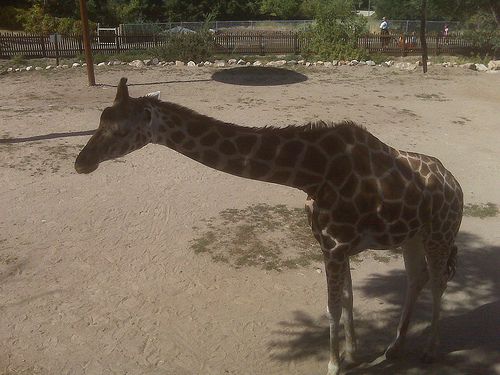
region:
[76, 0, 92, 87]
brown pole in ground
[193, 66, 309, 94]
shadow from the pole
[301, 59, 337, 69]
rocks on the ground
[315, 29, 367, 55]
green bush in front of fence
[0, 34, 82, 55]
brown fence behind trees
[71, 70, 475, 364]
giraffe on the sand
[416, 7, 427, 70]
tree in the ground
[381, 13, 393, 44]
person standing behind fence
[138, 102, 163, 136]
the giraffe's right ear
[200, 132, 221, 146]
brown spot on giraffe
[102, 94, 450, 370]
giraffe in the zoo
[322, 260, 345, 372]
leg of the giraffe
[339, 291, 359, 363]
leg of the giraffe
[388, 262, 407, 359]
leg of the giraffe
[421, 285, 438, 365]
leg of the giraffe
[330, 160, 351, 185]
spot on the giraffe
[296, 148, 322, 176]
spot on the giraffe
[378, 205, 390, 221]
spot on the giraffe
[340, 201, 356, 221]
spot on the giraffe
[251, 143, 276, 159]
spot on the giraffe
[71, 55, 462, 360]
giraffe at the zoo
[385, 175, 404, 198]
spot on the giraffe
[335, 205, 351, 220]
spot on the giraffe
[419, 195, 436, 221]
spot on the giraffe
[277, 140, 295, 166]
spot on the giraffe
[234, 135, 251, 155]
spot on the giraffe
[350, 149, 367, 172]
spot on the giraffe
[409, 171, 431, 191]
spot on the giraffe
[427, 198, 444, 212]
spot on the giraffe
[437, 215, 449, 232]
spot on the giraffe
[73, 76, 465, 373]
a giraffe at the zoo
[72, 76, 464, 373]
a giraffe standing under tree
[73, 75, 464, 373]
a giraffe in a national park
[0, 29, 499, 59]
a fence to contain the giraffe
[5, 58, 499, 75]
stones in front of the fence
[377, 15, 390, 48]
a woman on the other side of fence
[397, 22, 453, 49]
children on the other side of the fence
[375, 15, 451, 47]
a mother and children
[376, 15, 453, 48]
children and the mother visiting the zoo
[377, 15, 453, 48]
a mother and young kids visiting the national park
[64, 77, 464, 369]
giraffe standing in the dirt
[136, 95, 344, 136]
hair along the neck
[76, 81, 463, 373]
a baby giraffe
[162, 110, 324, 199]
spots along the neck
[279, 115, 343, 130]
hair sticking up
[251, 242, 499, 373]
shadows on the ground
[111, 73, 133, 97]
tiny horns on top of the head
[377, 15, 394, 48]
person standing on the other side of the fence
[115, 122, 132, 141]
eye on the side of the head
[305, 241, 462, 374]
four skinny legs